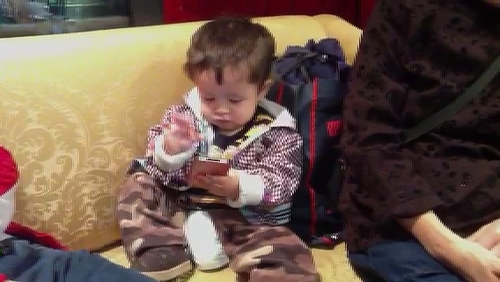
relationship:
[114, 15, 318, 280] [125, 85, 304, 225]
baby wearing jacket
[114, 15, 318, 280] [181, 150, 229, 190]
baby holding phone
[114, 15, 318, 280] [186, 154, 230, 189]
baby looking at phone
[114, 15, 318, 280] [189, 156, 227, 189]
baby looking at cell phone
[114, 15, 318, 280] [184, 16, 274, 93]
baby has hair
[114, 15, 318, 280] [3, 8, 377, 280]
baby sitting on couch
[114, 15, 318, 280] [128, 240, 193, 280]
baby wears shoe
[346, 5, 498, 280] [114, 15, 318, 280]
adult sitting next to baby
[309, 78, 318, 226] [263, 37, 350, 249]
line on backpack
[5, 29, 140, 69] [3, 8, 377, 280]
light on couch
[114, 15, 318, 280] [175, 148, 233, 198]
baby holding phone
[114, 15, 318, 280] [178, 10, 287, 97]
baby has hair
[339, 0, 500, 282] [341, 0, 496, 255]
adult has on a shirt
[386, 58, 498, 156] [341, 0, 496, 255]
strap on a shirt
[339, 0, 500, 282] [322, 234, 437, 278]
adult has blue pants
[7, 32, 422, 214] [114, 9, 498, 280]
sofa behind people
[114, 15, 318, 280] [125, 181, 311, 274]
baby wearing pants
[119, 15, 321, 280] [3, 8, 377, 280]
baby sitting on couch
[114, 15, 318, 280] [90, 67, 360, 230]
baby wearing jacket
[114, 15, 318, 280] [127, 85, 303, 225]
baby has coat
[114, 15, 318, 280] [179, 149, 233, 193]
baby holding cell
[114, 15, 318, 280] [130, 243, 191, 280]
baby has shoe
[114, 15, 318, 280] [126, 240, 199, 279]
baby has brown shoe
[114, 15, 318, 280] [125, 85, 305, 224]
baby wearing coat